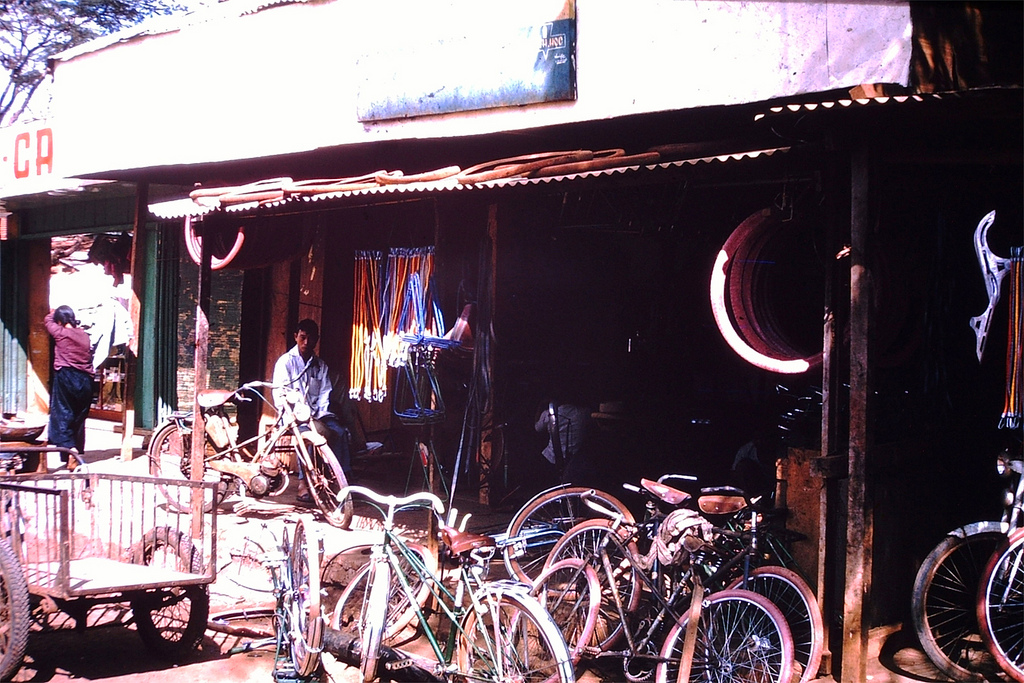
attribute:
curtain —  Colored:
[344, 266, 392, 400]